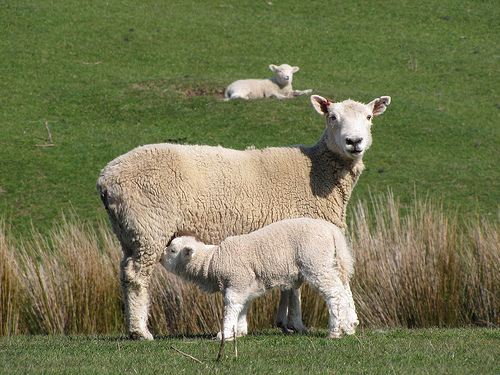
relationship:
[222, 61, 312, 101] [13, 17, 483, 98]
lamb in field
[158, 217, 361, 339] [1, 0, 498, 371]
lamb walking in field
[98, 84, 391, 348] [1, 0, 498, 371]
sheep walking in field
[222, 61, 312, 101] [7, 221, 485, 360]
lamb laying on field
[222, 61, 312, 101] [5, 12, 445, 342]
lamb standing in field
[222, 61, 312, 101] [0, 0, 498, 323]
lamb laying on field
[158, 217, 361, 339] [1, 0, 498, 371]
lamb standing on field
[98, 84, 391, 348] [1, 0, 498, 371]
sheep standing on field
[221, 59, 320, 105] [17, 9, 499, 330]
lamb lying in grass